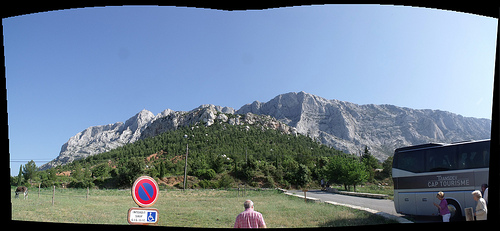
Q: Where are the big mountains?
A: Distance.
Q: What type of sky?
A: Clear.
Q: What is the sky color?
A: Blue.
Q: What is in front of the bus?
A: A mountain.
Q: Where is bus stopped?
A: Side of road.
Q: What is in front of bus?
A: Trees.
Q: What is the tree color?
A: Green.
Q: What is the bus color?
A: Silver and black.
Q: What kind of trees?
A: Pine trees.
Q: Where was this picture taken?
A: In a mountain range park.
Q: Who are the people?
A: Senior citizens.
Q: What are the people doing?
A: Looking at the mountains.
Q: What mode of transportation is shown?
A: A bus.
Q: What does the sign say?
A: Not handicap accessible/.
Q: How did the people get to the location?
A: By bus.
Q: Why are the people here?
A: To see the mountains.